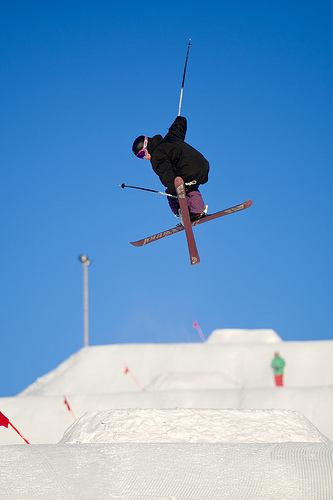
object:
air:
[76, 43, 132, 96]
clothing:
[270, 357, 286, 387]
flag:
[0, 411, 9, 428]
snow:
[56, 433, 206, 494]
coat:
[148, 132, 209, 212]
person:
[130, 118, 208, 225]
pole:
[177, 37, 195, 119]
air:
[21, 106, 87, 179]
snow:
[93, 429, 135, 496]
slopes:
[139, 363, 278, 498]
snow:
[37, 441, 104, 479]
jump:
[134, 179, 297, 342]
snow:
[266, 335, 297, 409]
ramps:
[81, 388, 306, 493]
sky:
[35, 45, 100, 126]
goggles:
[134, 146, 146, 160]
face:
[134, 143, 151, 159]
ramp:
[109, 381, 299, 497]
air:
[41, 30, 111, 124]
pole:
[83, 254, 95, 346]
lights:
[76, 249, 90, 269]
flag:
[121, 362, 132, 377]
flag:
[61, 393, 69, 408]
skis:
[128, 195, 254, 248]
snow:
[62, 405, 322, 444]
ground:
[0, 326, 319, 497]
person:
[269, 348, 288, 387]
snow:
[1, 326, 322, 498]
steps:
[2, 406, 322, 497]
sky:
[2, 1, 322, 395]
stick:
[119, 182, 178, 200]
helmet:
[131, 133, 149, 154]